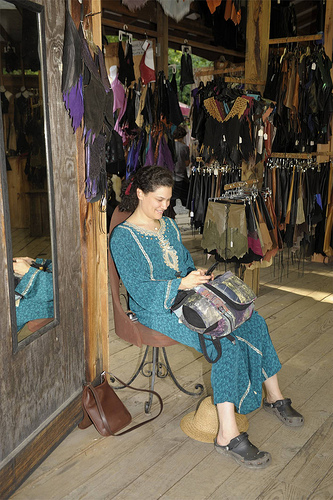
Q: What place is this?
A: It is a store.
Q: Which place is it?
A: It is a store.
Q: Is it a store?
A: Yes, it is a store.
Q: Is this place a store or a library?
A: It is a store.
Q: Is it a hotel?
A: No, it is a store.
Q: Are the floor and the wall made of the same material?
A: Yes, both the floor and the wall are made of wood.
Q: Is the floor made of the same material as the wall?
A: Yes, both the floor and the wall are made of wood.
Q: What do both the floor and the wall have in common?
A: The material, both the floor and the wall are wooden.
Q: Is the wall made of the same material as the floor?
A: Yes, both the wall and the floor are made of wood.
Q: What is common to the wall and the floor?
A: The material, both the wall and the floor are wooden.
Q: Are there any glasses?
A: No, there are no glasses.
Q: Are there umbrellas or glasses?
A: No, there are no glasses or umbrellas.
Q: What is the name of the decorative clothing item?
A: The clothing item is a dress.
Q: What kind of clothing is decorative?
A: The clothing is a dress.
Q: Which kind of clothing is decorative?
A: The clothing is a dress.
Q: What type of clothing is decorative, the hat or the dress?
A: The dress is decorative.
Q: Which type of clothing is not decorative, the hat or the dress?
A: The hat is not decorative.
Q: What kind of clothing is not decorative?
A: The clothing is a hat.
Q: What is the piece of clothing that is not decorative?
A: The clothing item is a hat.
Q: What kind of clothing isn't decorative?
A: The clothing is a hat.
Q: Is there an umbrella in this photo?
A: No, there are no umbrellas.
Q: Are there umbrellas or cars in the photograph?
A: No, there are no umbrellas or cars.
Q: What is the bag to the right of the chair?
A: The bag is a handbag.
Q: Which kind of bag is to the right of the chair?
A: The bag is a handbag.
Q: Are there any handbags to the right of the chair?
A: Yes, there is a handbag to the right of the chair.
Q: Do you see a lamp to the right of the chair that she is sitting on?
A: No, there is a handbag to the right of the chair.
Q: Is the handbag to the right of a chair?
A: Yes, the handbag is to the right of a chair.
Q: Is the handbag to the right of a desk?
A: No, the handbag is to the right of a chair.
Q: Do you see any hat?
A: Yes, there is a hat.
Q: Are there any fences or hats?
A: Yes, there is a hat.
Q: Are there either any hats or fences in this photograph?
A: Yes, there is a hat.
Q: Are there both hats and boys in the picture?
A: No, there is a hat but no boys.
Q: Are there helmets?
A: No, there are no helmets.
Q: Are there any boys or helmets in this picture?
A: No, there are no helmets or boys.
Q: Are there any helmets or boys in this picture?
A: No, there are no helmets or boys.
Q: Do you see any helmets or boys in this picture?
A: No, there are no helmets or boys.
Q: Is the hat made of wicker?
A: Yes, the hat is made of wicker.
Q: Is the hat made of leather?
A: No, the hat is made of wicker.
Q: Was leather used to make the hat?
A: No, the hat is made of wicker.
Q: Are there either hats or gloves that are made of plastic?
A: No, there is a hat but it is made of wicker.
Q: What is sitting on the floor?
A: The hat is sitting on the floor.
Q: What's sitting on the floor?
A: The hat is sitting on the floor.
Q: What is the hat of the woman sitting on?
A: The hat is sitting on the floor.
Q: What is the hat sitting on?
A: The hat is sitting on the floor.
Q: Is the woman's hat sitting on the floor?
A: Yes, the hat is sitting on the floor.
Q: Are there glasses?
A: No, there are no glasses.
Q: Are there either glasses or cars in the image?
A: No, there are no glasses or cars.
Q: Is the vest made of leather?
A: Yes, the vest is made of leather.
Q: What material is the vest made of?
A: The vest is made of leather.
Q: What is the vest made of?
A: The vest is made of leather.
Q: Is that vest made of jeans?
A: No, the vest is made of leather.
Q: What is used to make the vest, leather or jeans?
A: The vest is made of leather.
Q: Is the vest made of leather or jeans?
A: The vest is made of leather.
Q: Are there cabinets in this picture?
A: No, there are no cabinets.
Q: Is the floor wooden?
A: Yes, the floor is wooden.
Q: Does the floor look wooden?
A: Yes, the floor is wooden.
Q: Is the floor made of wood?
A: Yes, the floor is made of wood.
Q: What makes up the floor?
A: The floor is made of wood.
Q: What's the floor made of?
A: The floor is made of wood.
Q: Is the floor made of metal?
A: No, the floor is made of wood.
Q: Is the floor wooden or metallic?
A: The floor is wooden.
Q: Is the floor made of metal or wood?
A: The floor is made of wood.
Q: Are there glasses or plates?
A: No, there are no glasses or plates.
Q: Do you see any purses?
A: Yes, there is a purse.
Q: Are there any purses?
A: Yes, there is a purse.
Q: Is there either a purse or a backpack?
A: Yes, there is a purse.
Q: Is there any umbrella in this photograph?
A: No, there are no umbrellas.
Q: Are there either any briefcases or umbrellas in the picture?
A: No, there are no umbrellas or briefcases.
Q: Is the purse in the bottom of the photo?
A: Yes, the purse is in the bottom of the image.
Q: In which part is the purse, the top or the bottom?
A: The purse is in the bottom of the image.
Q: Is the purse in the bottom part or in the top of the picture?
A: The purse is in the bottom of the image.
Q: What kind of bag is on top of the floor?
A: The bag is a purse.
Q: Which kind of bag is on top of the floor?
A: The bag is a purse.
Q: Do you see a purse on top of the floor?
A: Yes, there is a purse on top of the floor.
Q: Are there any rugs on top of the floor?
A: No, there is a purse on top of the floor.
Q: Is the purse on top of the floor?
A: Yes, the purse is on top of the floor.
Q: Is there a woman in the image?
A: Yes, there is a woman.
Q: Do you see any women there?
A: Yes, there is a woman.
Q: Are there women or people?
A: Yes, there is a woman.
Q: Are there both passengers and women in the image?
A: No, there is a woman but no passengers.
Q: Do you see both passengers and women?
A: No, there is a woman but no passengers.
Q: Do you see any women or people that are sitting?
A: Yes, the woman is sitting.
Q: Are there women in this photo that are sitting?
A: Yes, there is a woman that is sitting.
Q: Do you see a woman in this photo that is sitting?
A: Yes, there is a woman that is sitting.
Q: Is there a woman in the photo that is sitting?
A: Yes, there is a woman that is sitting.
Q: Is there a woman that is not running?
A: Yes, there is a woman that is sitting.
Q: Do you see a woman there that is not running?
A: Yes, there is a woman that is sitting .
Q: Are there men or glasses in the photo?
A: No, there are no glasses or men.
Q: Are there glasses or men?
A: No, there are no glasses or men.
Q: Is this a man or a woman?
A: This is a woman.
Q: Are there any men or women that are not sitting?
A: No, there is a woman but she is sitting.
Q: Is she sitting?
A: Yes, the woman is sitting.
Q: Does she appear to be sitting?
A: Yes, the woman is sitting.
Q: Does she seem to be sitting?
A: Yes, the woman is sitting.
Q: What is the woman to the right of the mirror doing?
A: The woman is sitting.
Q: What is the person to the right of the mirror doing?
A: The woman is sitting.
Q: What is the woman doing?
A: The woman is sitting.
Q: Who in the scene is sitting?
A: The woman is sitting.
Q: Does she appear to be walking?
A: No, the woman is sitting.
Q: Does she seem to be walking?
A: No, the woman is sitting.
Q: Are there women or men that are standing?
A: No, there is a woman but she is sitting.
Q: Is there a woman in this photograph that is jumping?
A: No, there is a woman but she is sitting.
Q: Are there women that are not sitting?
A: No, there is a woman but she is sitting.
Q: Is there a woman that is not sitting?
A: No, there is a woman but she is sitting.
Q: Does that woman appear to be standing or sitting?
A: The woman is sitting.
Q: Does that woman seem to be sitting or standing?
A: The woman is sitting.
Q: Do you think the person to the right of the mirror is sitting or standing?
A: The woman is sitting.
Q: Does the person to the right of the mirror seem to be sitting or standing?
A: The woman is sitting.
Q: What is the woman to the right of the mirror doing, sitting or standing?
A: The woman is sitting.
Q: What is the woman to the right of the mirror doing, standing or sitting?
A: The woman is sitting.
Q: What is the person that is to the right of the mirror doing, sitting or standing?
A: The woman is sitting.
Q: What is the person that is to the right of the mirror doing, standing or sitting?
A: The woman is sitting.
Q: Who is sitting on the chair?
A: The woman is sitting on the chair.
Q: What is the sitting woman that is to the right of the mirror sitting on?
A: The woman is sitting on the chair.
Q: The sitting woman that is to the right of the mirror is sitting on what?
A: The woman is sitting on the chair.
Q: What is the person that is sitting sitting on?
A: The woman is sitting on the chair.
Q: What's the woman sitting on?
A: The woman is sitting on the chair.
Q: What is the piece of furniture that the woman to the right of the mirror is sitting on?
A: The piece of furniture is a chair.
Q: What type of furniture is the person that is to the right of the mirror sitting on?
A: The woman is sitting on the chair.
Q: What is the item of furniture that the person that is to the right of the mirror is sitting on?
A: The piece of furniture is a chair.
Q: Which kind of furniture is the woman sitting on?
A: The woman is sitting on the chair.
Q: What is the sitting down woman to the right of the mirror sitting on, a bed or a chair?
A: The woman is sitting on a chair.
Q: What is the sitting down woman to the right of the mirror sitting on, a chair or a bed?
A: The woman is sitting on a chair.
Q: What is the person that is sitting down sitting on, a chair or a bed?
A: The woman is sitting on a chair.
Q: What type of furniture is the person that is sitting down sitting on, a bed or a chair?
A: The woman is sitting on a chair.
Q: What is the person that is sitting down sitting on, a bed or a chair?
A: The woman is sitting on a chair.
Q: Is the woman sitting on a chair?
A: Yes, the woman is sitting on a chair.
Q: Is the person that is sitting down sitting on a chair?
A: Yes, the woman is sitting on a chair.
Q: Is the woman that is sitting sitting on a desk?
A: No, the woman is sitting on a chair.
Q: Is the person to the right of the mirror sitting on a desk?
A: No, the woman is sitting on a chair.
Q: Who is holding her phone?
A: The woman is holding the phone.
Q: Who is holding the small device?
A: The woman is holding the phone.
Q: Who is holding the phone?
A: The woman is holding the phone.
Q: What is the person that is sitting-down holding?
A: The woman is holding the telephone.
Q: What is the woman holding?
A: The woman is holding the telephone.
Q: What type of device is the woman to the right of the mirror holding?
A: The woman is holding the telephone.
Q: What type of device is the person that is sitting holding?
A: The woman is holding the telephone.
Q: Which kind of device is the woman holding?
A: The woman is holding the telephone.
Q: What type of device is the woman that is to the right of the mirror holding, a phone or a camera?
A: The woman is holding a phone.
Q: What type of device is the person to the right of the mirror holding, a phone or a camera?
A: The woman is holding a phone.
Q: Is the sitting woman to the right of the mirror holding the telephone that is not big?
A: Yes, the woman is holding the phone.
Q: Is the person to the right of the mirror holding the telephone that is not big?
A: Yes, the woman is holding the phone.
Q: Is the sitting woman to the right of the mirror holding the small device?
A: Yes, the woman is holding the phone.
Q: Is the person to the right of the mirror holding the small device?
A: Yes, the woman is holding the phone.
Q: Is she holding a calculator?
A: No, the woman is holding the phone.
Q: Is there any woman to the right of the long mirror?
A: Yes, there is a woman to the right of the mirror.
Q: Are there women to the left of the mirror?
A: No, the woman is to the right of the mirror.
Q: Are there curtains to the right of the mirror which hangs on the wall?
A: No, there is a woman to the right of the mirror.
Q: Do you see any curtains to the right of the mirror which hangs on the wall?
A: No, there is a woman to the right of the mirror.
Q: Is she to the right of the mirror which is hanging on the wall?
A: Yes, the woman is to the right of the mirror.